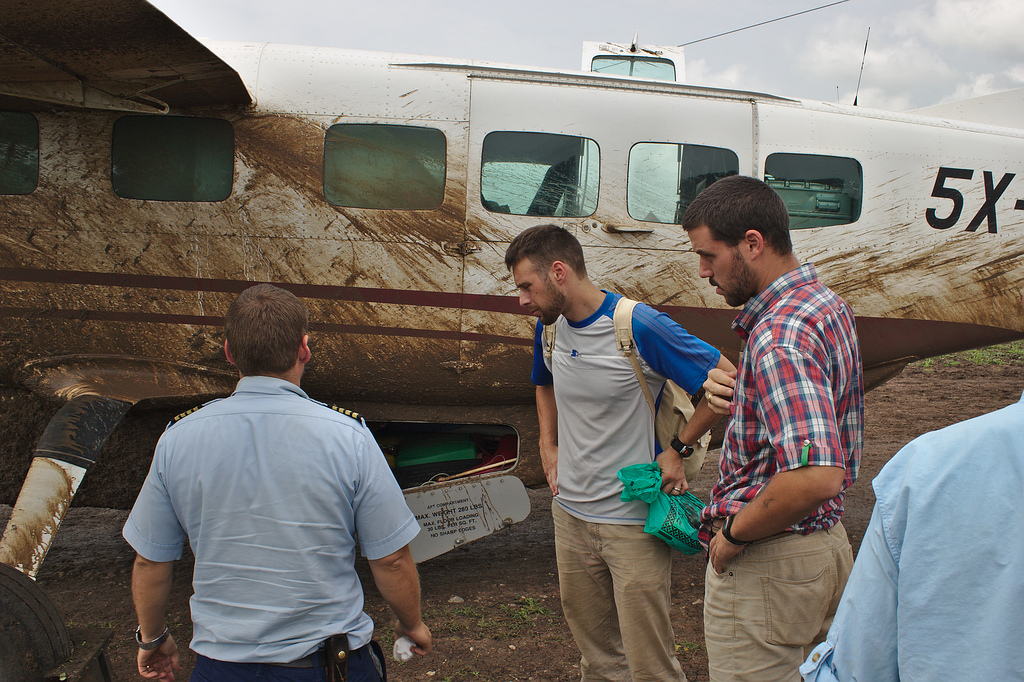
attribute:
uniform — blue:
[108, 370, 422, 664]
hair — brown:
[218, 269, 309, 378]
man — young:
[587, 156, 823, 429]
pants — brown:
[682, 480, 883, 664]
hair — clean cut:
[505, 225, 586, 278]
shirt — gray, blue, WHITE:
[527, 288, 722, 526]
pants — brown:
[551, 502, 688, 677]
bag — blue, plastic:
[615, 461, 708, 557]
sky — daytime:
[153, 1, 988, 122]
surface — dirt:
[6, 348, 990, 677]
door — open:
[402, 471, 534, 564]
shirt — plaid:
[698, 260, 863, 542]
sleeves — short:
[752, 344, 846, 468]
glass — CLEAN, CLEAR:
[590, 55, 671, 81]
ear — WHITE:
[547, 256, 569, 285]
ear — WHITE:
[744, 221, 768, 263]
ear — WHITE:
[299, 329, 313, 356]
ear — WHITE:
[219, 327, 233, 375]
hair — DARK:
[506, 221, 586, 280]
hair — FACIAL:
[526, 277, 561, 323]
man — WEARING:
[502, 217, 742, 648]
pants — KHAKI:
[545, 500, 679, 656]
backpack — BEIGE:
[642, 385, 725, 461]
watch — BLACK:
[668, 424, 697, 459]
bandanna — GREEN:
[610, 458, 710, 549]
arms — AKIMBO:
[638, 305, 742, 472]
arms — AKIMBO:
[525, 323, 562, 484]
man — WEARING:
[675, 169, 863, 660]